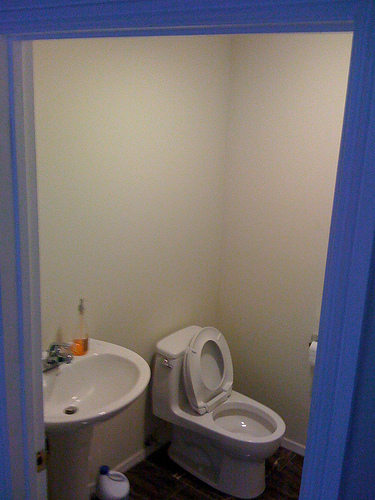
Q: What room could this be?
A: It is a bathroom.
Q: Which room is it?
A: It is a bathroom.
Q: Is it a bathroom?
A: Yes, it is a bathroom.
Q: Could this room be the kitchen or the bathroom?
A: It is the bathroom.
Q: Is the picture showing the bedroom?
A: No, the picture is showing the bathroom.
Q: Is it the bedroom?
A: No, it is the bathroom.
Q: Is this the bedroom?
A: No, it is the bathroom.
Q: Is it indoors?
A: Yes, it is indoors.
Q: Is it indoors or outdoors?
A: It is indoors.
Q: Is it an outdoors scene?
A: No, it is indoors.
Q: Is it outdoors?
A: No, it is indoors.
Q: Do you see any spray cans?
A: No, there are no spray cans.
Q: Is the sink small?
A: Yes, the sink is small.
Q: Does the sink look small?
A: Yes, the sink is small.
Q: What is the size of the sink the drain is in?
A: The sink is small.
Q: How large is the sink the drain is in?
A: The sink is small.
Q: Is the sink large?
A: No, the sink is small.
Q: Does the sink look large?
A: No, the sink is small.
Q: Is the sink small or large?
A: The sink is small.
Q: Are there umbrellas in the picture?
A: No, there are no umbrellas.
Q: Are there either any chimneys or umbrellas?
A: No, there are no umbrellas or chimneys.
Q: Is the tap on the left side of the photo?
A: Yes, the tap is on the left of the image.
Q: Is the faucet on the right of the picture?
A: No, the faucet is on the left of the image.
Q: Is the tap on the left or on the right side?
A: The tap is on the left of the image.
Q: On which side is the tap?
A: The tap is on the left of the image.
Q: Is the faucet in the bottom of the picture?
A: Yes, the faucet is in the bottom of the image.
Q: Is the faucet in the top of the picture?
A: No, the faucet is in the bottom of the image.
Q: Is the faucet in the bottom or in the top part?
A: The faucet is in the bottom of the image.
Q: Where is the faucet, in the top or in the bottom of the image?
A: The faucet is in the bottom of the image.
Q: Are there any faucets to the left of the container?
A: Yes, there is a faucet to the left of the container.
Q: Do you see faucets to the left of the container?
A: Yes, there is a faucet to the left of the container.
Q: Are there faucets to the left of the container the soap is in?
A: Yes, there is a faucet to the left of the container.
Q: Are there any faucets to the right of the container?
A: No, the faucet is to the left of the container.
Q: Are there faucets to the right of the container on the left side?
A: No, the faucet is to the left of the container.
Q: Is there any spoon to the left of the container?
A: No, there is a faucet to the left of the container.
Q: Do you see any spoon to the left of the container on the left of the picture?
A: No, there is a faucet to the left of the container.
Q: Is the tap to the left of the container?
A: Yes, the tap is to the left of the container.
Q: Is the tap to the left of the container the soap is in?
A: Yes, the tap is to the left of the container.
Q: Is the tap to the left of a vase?
A: No, the tap is to the left of the container.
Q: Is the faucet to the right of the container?
A: No, the faucet is to the left of the container.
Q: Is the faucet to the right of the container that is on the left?
A: No, the faucet is to the left of the container.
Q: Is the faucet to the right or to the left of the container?
A: The faucet is to the left of the container.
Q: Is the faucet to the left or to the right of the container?
A: The faucet is to the left of the container.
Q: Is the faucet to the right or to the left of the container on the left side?
A: The faucet is to the left of the container.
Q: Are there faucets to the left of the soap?
A: Yes, there is a faucet to the left of the soap.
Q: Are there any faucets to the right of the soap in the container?
A: No, the faucet is to the left of the soap.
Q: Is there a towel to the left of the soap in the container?
A: No, there is a faucet to the left of the soap.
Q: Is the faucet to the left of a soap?
A: Yes, the faucet is to the left of a soap.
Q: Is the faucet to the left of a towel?
A: No, the faucet is to the left of a soap.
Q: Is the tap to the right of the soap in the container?
A: No, the tap is to the left of the soap.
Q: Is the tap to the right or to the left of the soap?
A: The tap is to the left of the soap.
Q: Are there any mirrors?
A: No, there are no mirrors.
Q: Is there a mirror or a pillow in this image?
A: No, there are no mirrors or pillows.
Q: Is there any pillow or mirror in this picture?
A: No, there are no mirrors or pillows.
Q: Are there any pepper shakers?
A: No, there are no pepper shakers.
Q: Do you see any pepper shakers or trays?
A: No, there are no pepper shakers or trays.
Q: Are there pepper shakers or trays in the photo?
A: No, there are no pepper shakers or trays.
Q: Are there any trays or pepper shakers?
A: No, there are no pepper shakers or trays.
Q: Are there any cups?
A: No, there are no cups.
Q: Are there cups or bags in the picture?
A: No, there are no cups or bags.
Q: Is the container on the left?
A: Yes, the container is on the left of the image.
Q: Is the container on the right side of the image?
A: No, the container is on the left of the image.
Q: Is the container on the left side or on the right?
A: The container is on the left of the image.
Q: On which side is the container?
A: The container is on the left of the image.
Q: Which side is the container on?
A: The container is on the left of the image.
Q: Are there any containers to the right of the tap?
A: Yes, there is a container to the right of the tap.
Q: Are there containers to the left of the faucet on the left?
A: No, the container is to the right of the faucet.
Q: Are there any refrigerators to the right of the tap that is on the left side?
A: No, there is a container to the right of the faucet.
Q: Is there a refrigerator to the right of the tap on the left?
A: No, there is a container to the right of the faucet.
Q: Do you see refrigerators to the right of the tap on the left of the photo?
A: No, there is a container to the right of the faucet.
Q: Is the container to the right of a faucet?
A: Yes, the container is to the right of a faucet.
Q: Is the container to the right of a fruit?
A: No, the container is to the right of a faucet.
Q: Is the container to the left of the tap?
A: No, the container is to the right of the tap.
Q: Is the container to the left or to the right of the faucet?
A: The container is to the right of the faucet.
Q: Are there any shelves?
A: No, there are no shelves.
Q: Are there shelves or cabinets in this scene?
A: No, there are no shelves or cabinets.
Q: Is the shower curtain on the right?
A: Yes, the shower curtain is on the right of the image.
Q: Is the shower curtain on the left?
A: No, the shower curtain is on the right of the image.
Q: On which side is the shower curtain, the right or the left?
A: The shower curtain is on the right of the image.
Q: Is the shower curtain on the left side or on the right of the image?
A: The shower curtain is on the right of the image.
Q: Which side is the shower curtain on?
A: The shower curtain is on the right of the image.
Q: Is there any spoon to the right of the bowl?
A: No, there is a shower curtain to the right of the bowl.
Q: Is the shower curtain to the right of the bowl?
A: Yes, the shower curtain is to the right of the bowl.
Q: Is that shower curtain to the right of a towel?
A: No, the shower curtain is to the right of the bowl.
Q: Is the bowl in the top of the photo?
A: No, the bowl is in the bottom of the image.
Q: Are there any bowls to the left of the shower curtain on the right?
A: Yes, there is a bowl to the left of the shower curtain.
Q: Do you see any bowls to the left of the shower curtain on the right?
A: Yes, there is a bowl to the left of the shower curtain.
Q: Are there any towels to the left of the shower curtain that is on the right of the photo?
A: No, there is a bowl to the left of the shower curtain.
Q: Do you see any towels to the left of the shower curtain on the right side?
A: No, there is a bowl to the left of the shower curtain.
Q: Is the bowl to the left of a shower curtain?
A: Yes, the bowl is to the left of a shower curtain.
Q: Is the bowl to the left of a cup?
A: No, the bowl is to the left of a shower curtain.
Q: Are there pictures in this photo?
A: No, there are no pictures.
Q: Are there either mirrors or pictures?
A: No, there are no pictures or mirrors.